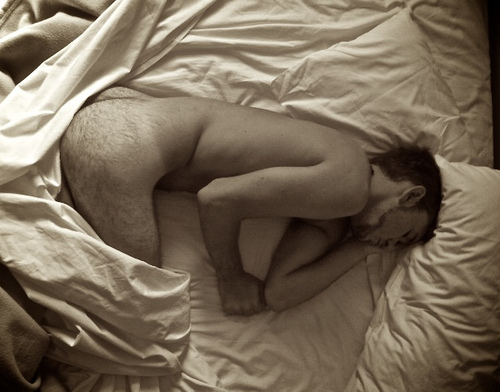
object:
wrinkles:
[350, 188, 500, 391]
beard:
[355, 210, 395, 240]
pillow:
[342, 153, 500, 391]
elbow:
[197, 191, 216, 212]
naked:
[61, 87, 442, 315]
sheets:
[0, 0, 500, 391]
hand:
[348, 238, 390, 258]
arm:
[198, 166, 367, 272]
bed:
[0, 0, 499, 390]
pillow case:
[345, 151, 497, 390]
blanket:
[0, 0, 114, 391]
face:
[355, 209, 425, 249]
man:
[60, 86, 441, 316]